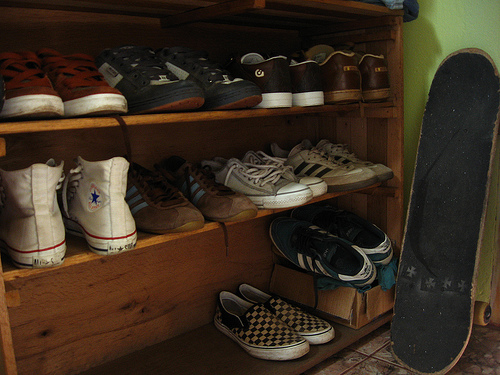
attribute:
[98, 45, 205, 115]
shoe — black, red, tan, white, brown, blue, checkered, grey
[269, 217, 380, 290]
shoe — blue, brown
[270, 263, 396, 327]
box — cardboard, small, brown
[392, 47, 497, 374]
skateboard — leaning, black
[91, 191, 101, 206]
logo — blue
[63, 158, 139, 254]
shoe — white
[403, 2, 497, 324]
wall — green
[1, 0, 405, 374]
shelf — wooden, brown, wood